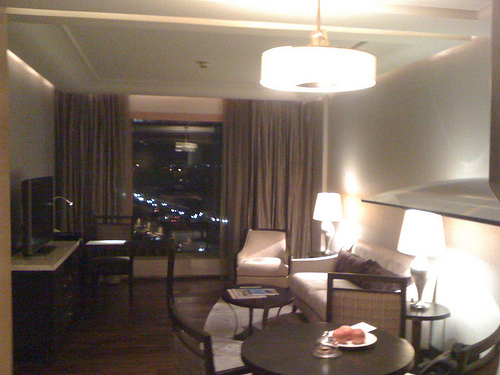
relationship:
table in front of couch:
[223, 282, 296, 338] [287, 238, 418, 320]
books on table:
[247, 287, 277, 295] [218, 284, 295, 332]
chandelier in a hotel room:
[258, 42, 379, 96] [0, 0, 500, 375]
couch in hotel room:
[285, 228, 447, 326] [10, 6, 492, 372]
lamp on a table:
[400, 210, 446, 315] [239, 321, 416, 373]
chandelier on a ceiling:
[258, 32, 396, 97] [6, 6, 490, 96]